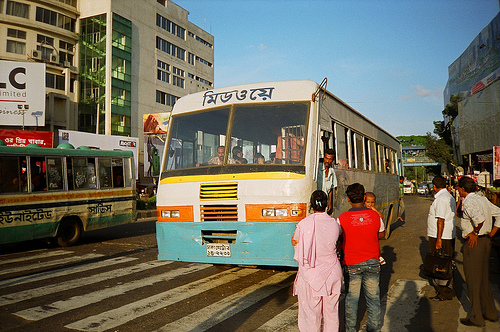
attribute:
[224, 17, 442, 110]
sky — clear, blue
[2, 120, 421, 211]
these — buses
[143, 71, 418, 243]
bus — big, low, white, multicolored, driving by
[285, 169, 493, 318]
people — waiting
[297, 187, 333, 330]
woman — pink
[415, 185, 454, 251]
shirt — white, red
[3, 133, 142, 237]
bus — green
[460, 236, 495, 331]
pants — brown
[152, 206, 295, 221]
headlights — orange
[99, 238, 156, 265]
line — yellow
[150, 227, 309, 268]
stripe — blue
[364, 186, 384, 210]
child — small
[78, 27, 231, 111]
building — modern looking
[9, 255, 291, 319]
lines — white, striped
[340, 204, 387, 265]
shirt — red